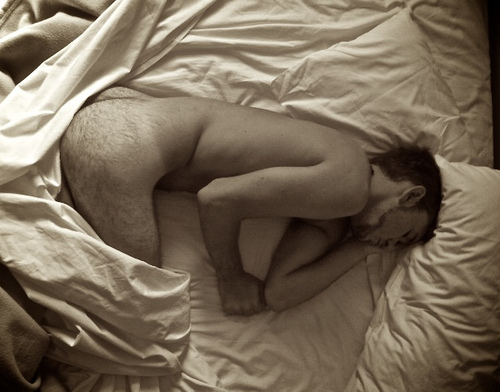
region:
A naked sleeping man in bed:
[15, 72, 450, 332]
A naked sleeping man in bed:
[46, 75, 446, 332]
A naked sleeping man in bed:
[46, 75, 451, 335]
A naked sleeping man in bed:
[48, 71, 453, 324]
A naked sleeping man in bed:
[43, 74, 463, 336]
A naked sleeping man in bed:
[51, 72, 446, 334]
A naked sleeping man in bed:
[47, 72, 447, 327]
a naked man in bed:
[24, 31, 490, 359]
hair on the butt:
[65, 100, 151, 199]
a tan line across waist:
[130, 79, 184, 196]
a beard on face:
[349, 199, 398, 271]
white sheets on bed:
[18, 19, 499, 372]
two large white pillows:
[284, 27, 499, 377]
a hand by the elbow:
[201, 264, 283, 329]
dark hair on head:
[363, 132, 442, 247]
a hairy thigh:
[87, 184, 167, 284]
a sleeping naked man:
[34, 54, 458, 365]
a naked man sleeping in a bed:
[43, 68, 454, 316]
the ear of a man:
[396, 177, 428, 211]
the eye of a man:
[396, 221, 413, 243]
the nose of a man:
[381, 233, 399, 253]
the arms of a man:
[192, 152, 358, 318]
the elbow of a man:
[256, 256, 295, 318]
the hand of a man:
[212, 270, 268, 316]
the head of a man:
[348, 135, 449, 260]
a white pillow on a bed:
[285, 10, 487, 151]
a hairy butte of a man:
[59, 82, 145, 172]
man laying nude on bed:
[76, 44, 447, 269]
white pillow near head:
[382, 178, 497, 360]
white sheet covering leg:
[23, 194, 245, 366]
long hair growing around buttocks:
[77, 106, 147, 190]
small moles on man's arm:
[251, 169, 278, 189]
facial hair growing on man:
[353, 198, 409, 248]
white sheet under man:
[144, 46, 467, 391]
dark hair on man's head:
[367, 135, 438, 185]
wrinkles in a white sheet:
[211, 313, 327, 388]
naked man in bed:
[9, 5, 497, 385]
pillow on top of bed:
[356, 156, 496, 390]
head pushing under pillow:
[360, 142, 448, 252]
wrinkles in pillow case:
[396, 182, 498, 389]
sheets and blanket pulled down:
[2, 58, 192, 388]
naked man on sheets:
[64, 82, 440, 316]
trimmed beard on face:
[353, 202, 398, 238]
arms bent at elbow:
[197, 165, 357, 314]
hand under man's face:
[350, 232, 393, 258]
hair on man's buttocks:
[60, 86, 143, 236]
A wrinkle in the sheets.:
[207, 345, 259, 375]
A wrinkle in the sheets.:
[256, 341, 326, 367]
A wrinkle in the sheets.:
[233, 76, 283, 105]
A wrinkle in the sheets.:
[205, 72, 240, 101]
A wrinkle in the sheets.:
[178, 60, 232, 85]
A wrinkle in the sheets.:
[188, 37, 298, 77]